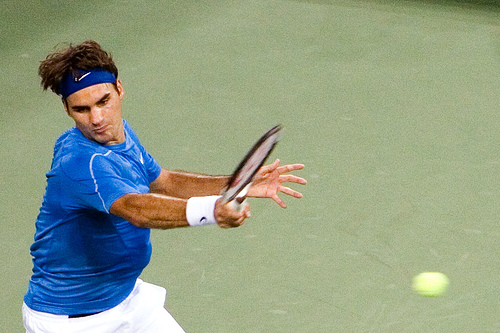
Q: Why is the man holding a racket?
A: To hit tennis ball.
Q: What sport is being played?
A: Tennis.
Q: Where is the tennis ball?
A: In the air.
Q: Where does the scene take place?
A: On a tennis court.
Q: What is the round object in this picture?
A: A tennis ball.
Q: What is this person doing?
A: Playing tennis.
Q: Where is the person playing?
A: At a tennis court.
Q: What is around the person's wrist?
A: A sweat band.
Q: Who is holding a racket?
A: A tennis player.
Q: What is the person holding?
A: A tennis racket.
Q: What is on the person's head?
A: A sweat band.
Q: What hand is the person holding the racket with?
A: The right hand.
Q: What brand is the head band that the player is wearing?
A: Nike.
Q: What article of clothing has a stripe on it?
A: A shirt.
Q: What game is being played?
A: Tennis.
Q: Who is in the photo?
A: A player.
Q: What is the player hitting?
A: A ball.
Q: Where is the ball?
A: In the air.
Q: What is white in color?
A: Shorts.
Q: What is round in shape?
A: The ball.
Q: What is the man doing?
A: Playing tennis.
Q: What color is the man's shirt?
A: Blue.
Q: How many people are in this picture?
A: One.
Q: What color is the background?
A: Green.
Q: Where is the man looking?
A: Down.